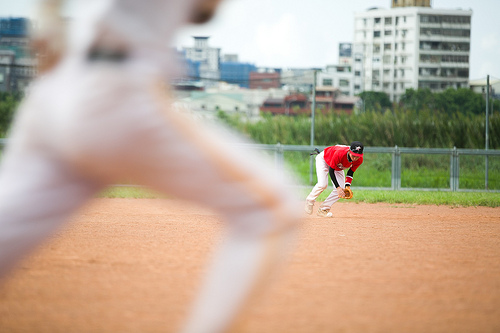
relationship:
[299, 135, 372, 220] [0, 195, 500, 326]
player on field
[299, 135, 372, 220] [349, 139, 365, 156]
player wearing hat